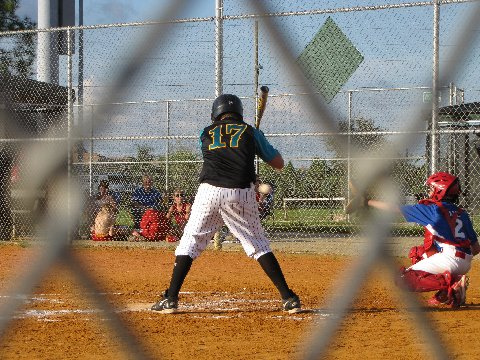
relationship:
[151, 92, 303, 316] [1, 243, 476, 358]
batter on field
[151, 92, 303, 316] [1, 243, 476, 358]
batter plays baseball on field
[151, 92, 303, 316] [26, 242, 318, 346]
batter in batters box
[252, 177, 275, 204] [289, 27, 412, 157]
baseball in air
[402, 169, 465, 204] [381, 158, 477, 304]
mask on catcher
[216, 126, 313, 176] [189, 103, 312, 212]
number on jersey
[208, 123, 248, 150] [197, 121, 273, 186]
number on shirt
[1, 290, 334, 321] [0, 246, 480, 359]
white line on dirt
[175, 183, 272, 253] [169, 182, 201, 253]
pants have stripes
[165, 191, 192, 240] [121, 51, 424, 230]
person located outside of fence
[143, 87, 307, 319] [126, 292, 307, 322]
batter standing at home plate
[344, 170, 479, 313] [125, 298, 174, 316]
catcher squatting at home plate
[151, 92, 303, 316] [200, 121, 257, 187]
batter wearing jersey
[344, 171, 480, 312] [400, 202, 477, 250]
catcher wearing jersey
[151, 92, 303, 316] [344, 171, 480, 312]
batter playing with catcher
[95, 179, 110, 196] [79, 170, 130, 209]
head of person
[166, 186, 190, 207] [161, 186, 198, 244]
head of person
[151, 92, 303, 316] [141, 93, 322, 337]
batter playing baseball